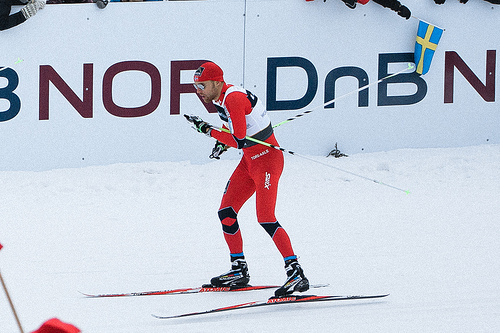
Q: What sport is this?
A: Skiing.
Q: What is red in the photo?
A: Snowsuit.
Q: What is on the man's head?
A: Hat.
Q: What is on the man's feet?
A: Boots.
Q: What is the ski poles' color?
A: It's black and white.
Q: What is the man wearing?
A: It's red and white.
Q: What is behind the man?
A: A sign.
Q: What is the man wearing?
A: A ski outfit.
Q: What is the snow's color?
A: It's white.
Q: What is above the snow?
A: A man.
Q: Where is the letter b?
A: On the sign.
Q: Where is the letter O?
A: On the sign.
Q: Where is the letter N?
A: On the sign.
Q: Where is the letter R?
A: On the sign.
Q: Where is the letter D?
A: On the sign.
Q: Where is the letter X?
A: On the uniform.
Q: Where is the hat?
A: On the man.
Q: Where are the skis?
A: On the man.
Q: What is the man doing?
A: Skiing.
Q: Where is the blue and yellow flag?
A: To the right of the skier.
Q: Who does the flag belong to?
A: Spectator.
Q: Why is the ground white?
A: Snow.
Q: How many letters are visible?
A: 8.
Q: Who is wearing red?
A: Skier.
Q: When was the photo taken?
A: Daytime.